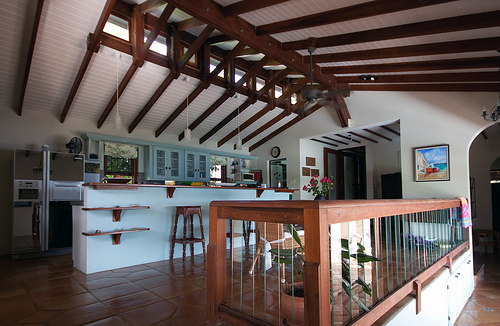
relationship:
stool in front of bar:
[170, 205, 209, 264] [70, 183, 298, 274]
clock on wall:
[267, 144, 283, 156] [242, 91, 498, 198]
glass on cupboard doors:
[129, 140, 222, 202] [147, 145, 216, 184]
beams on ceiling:
[57, 3, 497, 142] [66, 0, 350, 150]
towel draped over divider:
[444, 193, 481, 231] [303, 169, 472, 319]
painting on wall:
[416, 149, 447, 180] [242, 85, 498, 241]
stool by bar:
[164, 202, 209, 264] [58, 175, 309, 277]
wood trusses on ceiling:
[25, 7, 438, 154] [21, 9, 498, 161]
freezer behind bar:
[5, 139, 85, 257] [14, 140, 88, 251]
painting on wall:
[411, 141, 451, 184] [0, 0, 499, 263]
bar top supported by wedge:
[82, 178, 293, 193] [163, 187, 177, 199]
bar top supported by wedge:
[82, 178, 293, 193] [254, 190, 262, 196]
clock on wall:
[265, 148, 282, 160] [242, 91, 498, 198]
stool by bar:
[170, 205, 209, 264] [70, 183, 298, 274]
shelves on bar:
[80, 191, 153, 237] [70, 183, 298, 274]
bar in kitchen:
[70, 183, 298, 274] [3, 0, 499, 321]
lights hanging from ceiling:
[237, 138, 243, 150] [6, 0, 499, 140]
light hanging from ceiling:
[113, 113, 121, 128] [6, 0, 499, 140]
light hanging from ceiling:
[181, 125, 192, 142] [6, 0, 499, 140]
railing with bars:
[231, 226, 293, 284] [225, 211, 461, 310]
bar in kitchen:
[70, 183, 298, 274] [56, 140, 439, 318]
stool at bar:
[170, 205, 209, 264] [70, 183, 298, 274]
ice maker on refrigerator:
[14, 180, 46, 202] [9, 140, 81, 258]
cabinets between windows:
[152, 148, 184, 170] [105, 150, 137, 175]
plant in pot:
[264, 223, 383, 294] [277, 278, 332, 323]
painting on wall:
[411, 141, 451, 184] [390, 92, 493, 249]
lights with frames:
[92, 3, 304, 115] [3, 3, 488, 150]